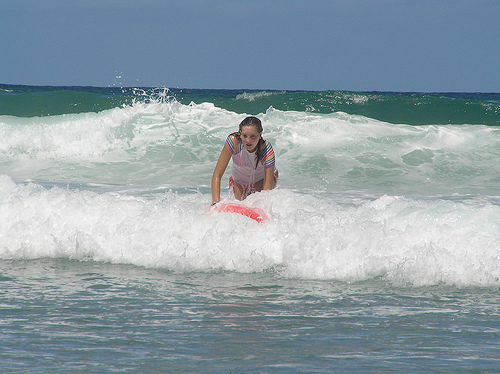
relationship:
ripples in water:
[178, 283, 203, 308] [14, 58, 481, 356]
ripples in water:
[69, 217, 189, 343] [57, 68, 474, 372]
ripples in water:
[165, 267, 217, 306] [33, 79, 460, 346]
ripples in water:
[113, 242, 226, 335] [49, 83, 480, 348]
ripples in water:
[130, 250, 208, 329] [35, 27, 408, 319]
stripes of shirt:
[204, 136, 274, 187] [191, 98, 319, 238]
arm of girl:
[210, 133, 233, 204] [194, 91, 331, 240]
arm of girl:
[185, 120, 240, 214] [187, 96, 307, 242]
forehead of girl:
[234, 100, 286, 180] [196, 93, 334, 272]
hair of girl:
[230, 100, 268, 142] [187, 96, 307, 242]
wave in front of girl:
[0, 86, 484, 294] [194, 92, 282, 222]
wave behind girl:
[3, 49, 483, 293] [188, 106, 289, 216]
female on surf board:
[211, 115, 281, 208] [195, 179, 295, 240]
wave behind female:
[0, 86, 484, 294] [211, 115, 281, 208]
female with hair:
[211, 115, 281, 208] [239, 101, 293, 143]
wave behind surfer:
[0, 86, 484, 294] [182, 80, 354, 319]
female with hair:
[211, 115, 281, 208] [245, 101, 275, 181]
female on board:
[203, 82, 321, 242] [194, 174, 289, 228]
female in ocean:
[211, 115, 281, 208] [17, 58, 481, 359]